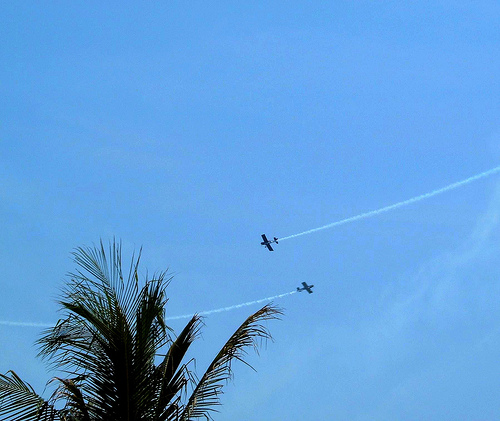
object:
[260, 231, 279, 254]
airplane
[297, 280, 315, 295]
plane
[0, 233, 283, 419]
tree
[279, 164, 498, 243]
line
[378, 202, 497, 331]
cloud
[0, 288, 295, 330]
white chemtrails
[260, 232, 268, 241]
wing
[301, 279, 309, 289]
wing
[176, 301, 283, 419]
palm leaves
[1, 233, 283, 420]
green palms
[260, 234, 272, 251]
wings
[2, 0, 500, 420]
sky